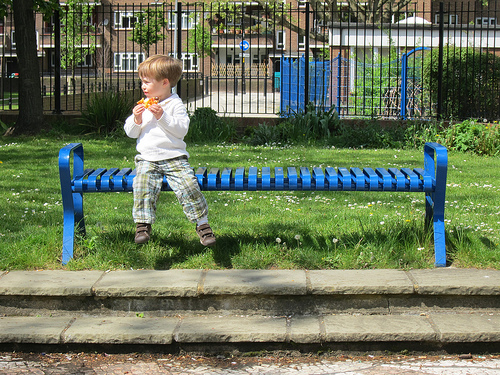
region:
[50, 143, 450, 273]
a long blue bench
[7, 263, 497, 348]
a concrete staircase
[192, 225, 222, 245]
a boy's shoe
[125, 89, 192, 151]
a boy's long sleeve white shirt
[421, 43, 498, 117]
a tall green bush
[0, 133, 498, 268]
a section of green grass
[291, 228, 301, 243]
a white flower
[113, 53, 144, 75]
a window of a building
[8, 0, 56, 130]
part of a tree branch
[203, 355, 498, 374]
white gravel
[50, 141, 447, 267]
Blue metal bench in grass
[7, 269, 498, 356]
Stone steps in front of bench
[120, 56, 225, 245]
Little boy sitting on bench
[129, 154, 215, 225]
Plaid pants on little boy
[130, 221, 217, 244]
Brown shoes on little boy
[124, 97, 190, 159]
White shirt on little boy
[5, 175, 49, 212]
White flowers in grass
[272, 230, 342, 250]
Dandelions with fluff in grass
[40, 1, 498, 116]
Long wrought iron fence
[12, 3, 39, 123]
Tree trunk in front of fence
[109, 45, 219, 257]
Small child eatting pizza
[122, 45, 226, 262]
Small child sitting on a blue bench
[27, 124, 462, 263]
Bright blue bench with child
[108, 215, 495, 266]
Shadow cast by blue bench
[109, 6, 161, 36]
White window to a building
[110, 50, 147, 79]
White window to a building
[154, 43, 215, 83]
White window to a building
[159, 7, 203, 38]
White window to a building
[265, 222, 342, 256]
White flowers in green grass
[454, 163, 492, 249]
White flowers in green grass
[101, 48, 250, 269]
"The little boy is sitting"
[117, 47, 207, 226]
"The little boy is eating"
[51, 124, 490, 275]
"The bench is blue"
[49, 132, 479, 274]
"A blue, metal bench"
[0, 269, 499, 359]
"Two steps can be seen here"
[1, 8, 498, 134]
"A black fence"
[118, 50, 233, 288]
"His little feet aren't touching the ground"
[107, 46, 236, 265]
"He is wearing pants"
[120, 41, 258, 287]
"He has his head turned"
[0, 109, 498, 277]
"The grass is green"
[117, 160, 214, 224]
Blue and green plaid pants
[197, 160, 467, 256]
Metal Blue Painted Bench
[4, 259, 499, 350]
Cement Slab two level Steps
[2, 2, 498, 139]
Tall Cast Iron Fence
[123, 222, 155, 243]
Right Brown Child Shoe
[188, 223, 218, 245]
Left Brown Child Shoe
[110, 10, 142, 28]
Rectangle Shaped Window On Builing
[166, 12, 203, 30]
Rectangle Shaped Window On Builing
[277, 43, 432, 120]
Blue Plastic Net Fence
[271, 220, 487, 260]
Over grown weeds and grass